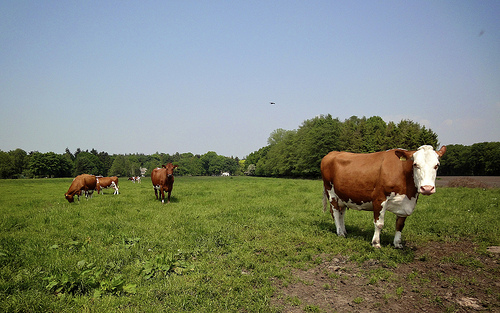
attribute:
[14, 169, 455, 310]
grass — green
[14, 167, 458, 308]
field — grass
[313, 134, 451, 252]
cow — walking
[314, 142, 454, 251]
cow — brown and white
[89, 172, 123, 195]
cow — brown and white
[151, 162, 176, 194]
cow — brown and white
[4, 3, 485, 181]
sky — blue 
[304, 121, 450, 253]
cow — white, brown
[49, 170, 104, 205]
cow — brown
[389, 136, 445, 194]
head — cow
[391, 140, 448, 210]
head — cow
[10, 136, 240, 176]
trees — green leaves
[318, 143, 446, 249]
cow — brown, white